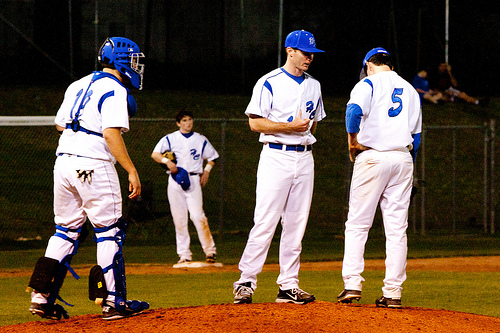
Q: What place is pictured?
A: It is a field.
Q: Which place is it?
A: It is a field.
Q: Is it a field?
A: Yes, it is a field.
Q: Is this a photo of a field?
A: Yes, it is showing a field.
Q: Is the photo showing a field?
A: Yes, it is showing a field.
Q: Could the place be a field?
A: Yes, it is a field.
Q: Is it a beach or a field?
A: It is a field.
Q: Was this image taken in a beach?
A: No, the picture was taken in a field.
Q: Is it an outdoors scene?
A: Yes, it is outdoors.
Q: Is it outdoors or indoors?
A: It is outdoors.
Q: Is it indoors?
A: No, it is outdoors.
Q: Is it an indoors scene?
A: No, it is outdoors.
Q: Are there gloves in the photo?
A: Yes, there are gloves.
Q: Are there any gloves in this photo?
A: Yes, there are gloves.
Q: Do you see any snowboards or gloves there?
A: Yes, there are gloves.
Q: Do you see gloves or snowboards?
A: Yes, there are gloves.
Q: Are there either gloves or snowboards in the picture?
A: Yes, there are gloves.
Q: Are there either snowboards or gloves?
A: Yes, there are gloves.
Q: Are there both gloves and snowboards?
A: No, there are gloves but no snowboards.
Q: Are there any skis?
A: No, there are no skis.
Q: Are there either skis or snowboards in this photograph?
A: No, there are no skis or snowboards.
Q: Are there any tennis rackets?
A: No, there are no tennis rackets.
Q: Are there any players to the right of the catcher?
A: Yes, there is a player to the right of the catcher.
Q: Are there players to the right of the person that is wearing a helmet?
A: Yes, there is a player to the right of the catcher.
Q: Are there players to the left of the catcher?
A: No, the player is to the right of the catcher.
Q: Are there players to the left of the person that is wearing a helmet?
A: No, the player is to the right of the catcher.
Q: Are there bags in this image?
A: No, there are no bags.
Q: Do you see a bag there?
A: No, there are no bags.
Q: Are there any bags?
A: No, there are no bags.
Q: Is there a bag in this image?
A: No, there are no bags.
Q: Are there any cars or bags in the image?
A: No, there are no bags or cars.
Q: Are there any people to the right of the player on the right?
A: Yes, there are people to the right of the player.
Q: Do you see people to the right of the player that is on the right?
A: Yes, there are people to the right of the player.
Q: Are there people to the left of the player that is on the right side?
A: No, the people are to the right of the player.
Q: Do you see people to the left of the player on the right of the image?
A: No, the people are to the right of the player.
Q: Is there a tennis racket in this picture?
A: No, there are no rackets.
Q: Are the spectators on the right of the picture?
A: Yes, the spectators are on the right of the image.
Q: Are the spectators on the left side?
A: No, the spectators are on the right of the image.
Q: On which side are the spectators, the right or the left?
A: The spectators are on the right of the image.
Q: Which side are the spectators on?
A: The spectators are on the right of the image.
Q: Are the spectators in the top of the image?
A: Yes, the spectators are in the top of the image.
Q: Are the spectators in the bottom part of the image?
A: No, the spectators are in the top of the image.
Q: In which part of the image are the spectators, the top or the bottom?
A: The spectators are in the top of the image.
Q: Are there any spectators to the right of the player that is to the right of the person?
A: Yes, there are spectators to the right of the player.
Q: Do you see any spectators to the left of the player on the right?
A: No, the spectators are to the right of the player.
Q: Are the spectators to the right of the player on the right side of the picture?
A: Yes, the spectators are to the right of the player.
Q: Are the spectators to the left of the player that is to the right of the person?
A: No, the spectators are to the right of the player.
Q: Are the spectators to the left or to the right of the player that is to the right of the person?
A: The spectators are to the right of the player.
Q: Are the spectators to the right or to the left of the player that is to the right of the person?
A: The spectators are to the right of the player.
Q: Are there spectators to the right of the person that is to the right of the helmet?
A: Yes, there are spectators to the right of the person.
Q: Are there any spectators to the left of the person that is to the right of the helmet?
A: No, the spectators are to the right of the person.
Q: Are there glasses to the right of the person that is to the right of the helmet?
A: No, there are spectators to the right of the person.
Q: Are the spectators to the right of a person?
A: Yes, the spectators are to the right of a person.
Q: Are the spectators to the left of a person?
A: No, the spectators are to the right of a person.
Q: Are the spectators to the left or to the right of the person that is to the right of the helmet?
A: The spectators are to the right of the person.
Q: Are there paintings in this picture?
A: No, there are no paintings.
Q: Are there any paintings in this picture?
A: No, there are no paintings.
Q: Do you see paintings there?
A: No, there are no paintings.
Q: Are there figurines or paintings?
A: No, there are no paintings or figurines.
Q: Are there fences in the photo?
A: Yes, there is a fence.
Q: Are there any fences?
A: Yes, there is a fence.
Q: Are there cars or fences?
A: Yes, there is a fence.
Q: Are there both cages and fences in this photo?
A: No, there is a fence but no cages.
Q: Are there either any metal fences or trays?
A: Yes, there is a metal fence.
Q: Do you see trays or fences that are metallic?
A: Yes, the fence is metallic.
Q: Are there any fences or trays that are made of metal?
A: Yes, the fence is made of metal.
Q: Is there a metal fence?
A: Yes, there is a fence that is made of metal.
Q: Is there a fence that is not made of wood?
A: Yes, there is a fence that is made of metal.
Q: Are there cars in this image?
A: No, there are no cars.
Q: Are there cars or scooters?
A: No, there are no cars or scooters.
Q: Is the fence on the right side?
A: Yes, the fence is on the right of the image.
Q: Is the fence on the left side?
A: No, the fence is on the right of the image.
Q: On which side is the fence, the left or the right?
A: The fence is on the right of the image.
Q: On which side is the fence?
A: The fence is on the right of the image.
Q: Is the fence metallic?
A: Yes, the fence is metallic.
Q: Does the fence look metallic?
A: Yes, the fence is metallic.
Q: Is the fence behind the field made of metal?
A: Yes, the fence is made of metal.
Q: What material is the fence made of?
A: The fence is made of metal.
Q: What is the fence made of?
A: The fence is made of metal.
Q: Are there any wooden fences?
A: No, there is a fence but it is metallic.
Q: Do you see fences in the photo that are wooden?
A: No, there is a fence but it is metallic.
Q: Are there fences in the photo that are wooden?
A: No, there is a fence but it is metallic.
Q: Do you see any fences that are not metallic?
A: No, there is a fence but it is metallic.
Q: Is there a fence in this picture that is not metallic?
A: No, there is a fence but it is metallic.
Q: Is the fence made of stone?
A: No, the fence is made of metal.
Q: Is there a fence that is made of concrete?
A: No, there is a fence but it is made of metal.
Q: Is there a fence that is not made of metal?
A: No, there is a fence but it is made of metal.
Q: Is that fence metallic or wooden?
A: The fence is metallic.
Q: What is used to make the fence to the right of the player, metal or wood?
A: The fence is made of metal.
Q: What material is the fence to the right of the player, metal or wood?
A: The fence is made of metal.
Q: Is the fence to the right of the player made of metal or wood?
A: The fence is made of metal.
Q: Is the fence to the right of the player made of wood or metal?
A: The fence is made of metal.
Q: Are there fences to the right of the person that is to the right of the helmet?
A: Yes, there is a fence to the right of the person.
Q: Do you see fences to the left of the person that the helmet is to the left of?
A: No, the fence is to the right of the person.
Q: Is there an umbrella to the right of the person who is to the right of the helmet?
A: No, there is a fence to the right of the person.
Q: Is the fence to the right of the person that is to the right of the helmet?
A: Yes, the fence is to the right of the person.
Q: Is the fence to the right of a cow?
A: No, the fence is to the right of the person.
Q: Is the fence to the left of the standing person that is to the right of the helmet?
A: No, the fence is to the right of the person.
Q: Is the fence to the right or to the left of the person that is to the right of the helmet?
A: The fence is to the right of the person.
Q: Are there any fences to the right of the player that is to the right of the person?
A: Yes, there is a fence to the right of the player.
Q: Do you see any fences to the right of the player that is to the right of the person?
A: Yes, there is a fence to the right of the player.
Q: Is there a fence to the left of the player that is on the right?
A: No, the fence is to the right of the player.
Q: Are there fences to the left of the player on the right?
A: No, the fence is to the right of the player.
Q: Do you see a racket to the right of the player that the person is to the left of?
A: No, there is a fence to the right of the player.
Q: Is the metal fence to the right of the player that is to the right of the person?
A: Yes, the fence is to the right of the player.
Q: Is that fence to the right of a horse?
A: No, the fence is to the right of the player.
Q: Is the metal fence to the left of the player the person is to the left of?
A: No, the fence is to the right of the player.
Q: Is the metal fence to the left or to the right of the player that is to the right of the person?
A: The fence is to the right of the player.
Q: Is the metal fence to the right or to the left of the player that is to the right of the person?
A: The fence is to the right of the player.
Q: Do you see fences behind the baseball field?
A: Yes, there is a fence behind the field.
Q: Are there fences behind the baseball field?
A: Yes, there is a fence behind the field.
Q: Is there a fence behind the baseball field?
A: Yes, there is a fence behind the field.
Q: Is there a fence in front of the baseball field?
A: No, the fence is behind the field.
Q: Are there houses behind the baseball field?
A: No, there is a fence behind the field.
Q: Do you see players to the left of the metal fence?
A: Yes, there is a player to the left of the fence.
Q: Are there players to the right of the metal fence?
A: No, the player is to the left of the fence.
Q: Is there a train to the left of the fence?
A: No, there is a player to the left of the fence.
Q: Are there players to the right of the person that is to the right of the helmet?
A: Yes, there is a player to the right of the person.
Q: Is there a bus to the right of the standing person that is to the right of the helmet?
A: No, there is a player to the right of the person.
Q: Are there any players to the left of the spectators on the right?
A: Yes, there is a player to the left of the spectators.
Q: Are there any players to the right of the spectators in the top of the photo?
A: No, the player is to the left of the spectators.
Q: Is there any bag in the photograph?
A: No, there are no bags.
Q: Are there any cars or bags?
A: No, there are no bags or cars.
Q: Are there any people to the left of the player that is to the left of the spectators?
A: Yes, there is a person to the left of the player.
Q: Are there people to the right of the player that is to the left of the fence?
A: No, the person is to the left of the player.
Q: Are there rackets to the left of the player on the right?
A: No, there is a person to the left of the player.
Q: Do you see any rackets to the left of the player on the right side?
A: No, there is a person to the left of the player.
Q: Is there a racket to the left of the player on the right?
A: No, there is a person to the left of the player.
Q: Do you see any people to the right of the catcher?
A: Yes, there is a person to the right of the catcher.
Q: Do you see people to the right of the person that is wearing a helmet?
A: Yes, there is a person to the right of the catcher.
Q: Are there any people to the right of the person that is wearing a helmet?
A: Yes, there is a person to the right of the catcher.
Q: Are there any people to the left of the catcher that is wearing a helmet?
A: No, the person is to the right of the catcher.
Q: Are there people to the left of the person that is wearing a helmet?
A: No, the person is to the right of the catcher.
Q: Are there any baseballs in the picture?
A: Yes, there is a baseball.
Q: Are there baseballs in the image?
A: Yes, there is a baseball.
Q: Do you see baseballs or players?
A: Yes, there is a baseball.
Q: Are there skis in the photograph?
A: No, there are no skis.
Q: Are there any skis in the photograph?
A: No, there are no skis.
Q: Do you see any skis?
A: No, there are no skis.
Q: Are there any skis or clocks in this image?
A: No, there are no skis or clocks.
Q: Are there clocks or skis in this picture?
A: No, there are no skis or clocks.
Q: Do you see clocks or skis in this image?
A: No, there are no skis or clocks.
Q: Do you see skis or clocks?
A: No, there are no skis or clocks.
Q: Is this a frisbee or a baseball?
A: This is a baseball.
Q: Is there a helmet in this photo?
A: Yes, there is a helmet.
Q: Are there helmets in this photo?
A: Yes, there is a helmet.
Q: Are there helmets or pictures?
A: Yes, there is a helmet.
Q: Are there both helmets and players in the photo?
A: Yes, there are both a helmet and a player.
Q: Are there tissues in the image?
A: No, there are no tissues.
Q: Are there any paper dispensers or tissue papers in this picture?
A: No, there are no tissue papers or paper dispensers.